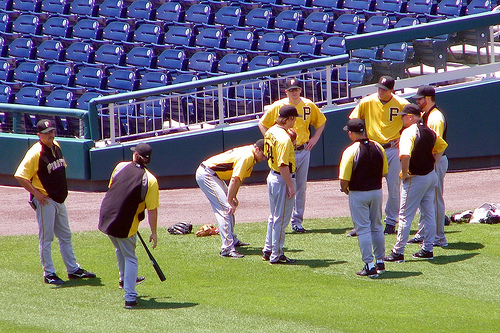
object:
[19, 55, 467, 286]
pirates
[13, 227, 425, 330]
field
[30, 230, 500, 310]
grass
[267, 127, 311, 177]
jersey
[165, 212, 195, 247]
mitt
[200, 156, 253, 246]
pants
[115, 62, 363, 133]
railings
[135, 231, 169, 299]
bat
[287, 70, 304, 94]
cap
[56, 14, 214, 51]
seating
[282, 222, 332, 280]
shadows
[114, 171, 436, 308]
ground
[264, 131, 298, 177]
shirt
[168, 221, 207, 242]
glove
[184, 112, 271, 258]
men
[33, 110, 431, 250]
group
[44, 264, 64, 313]
shoe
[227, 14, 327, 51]
seats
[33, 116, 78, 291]
man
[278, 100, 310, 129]
hat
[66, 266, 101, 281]
shoes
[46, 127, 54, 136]
sunglasses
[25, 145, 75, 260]
attire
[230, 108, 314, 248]
player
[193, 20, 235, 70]
chair